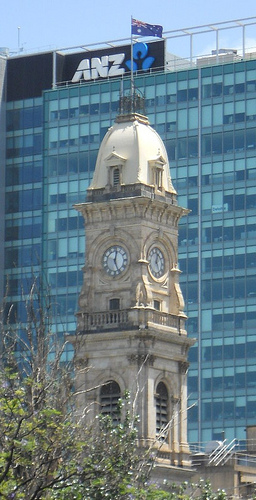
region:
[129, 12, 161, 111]
a national flag and pole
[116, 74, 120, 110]
a communication antenna on top of the tower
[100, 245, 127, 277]
the clock on the clock tower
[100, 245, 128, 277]
the clock display is 12:25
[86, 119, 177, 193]
the clock tower's roof dome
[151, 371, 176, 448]
an archway window with wood blinds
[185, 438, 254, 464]
metal safety hand rails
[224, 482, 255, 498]
a metal fence at the lower end of the clock tower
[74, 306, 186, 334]
a concrete balcony on the clock tower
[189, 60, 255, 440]
a building with many windows in the background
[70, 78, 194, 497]
Clock tower in front of sky scraper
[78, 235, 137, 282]
Clock saying five p.m.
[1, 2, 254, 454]
Sky scraper behind clock tower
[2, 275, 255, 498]
Tree in front of clock tower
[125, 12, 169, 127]
Russian or Canadian flag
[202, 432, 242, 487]
Set of stairs going up to the clock tower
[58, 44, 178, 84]
ANZ building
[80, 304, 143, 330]
Balcony of the clock tower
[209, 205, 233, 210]
Advertisement on the side of the building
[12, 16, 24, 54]
Flag pole on top of building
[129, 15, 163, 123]
Red white and blue flag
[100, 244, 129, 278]
Clock face showing that it is twelve twenty five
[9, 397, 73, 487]
Several tree branches with green leaves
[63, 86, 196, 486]
Old fashion clock tower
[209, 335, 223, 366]
Window on a building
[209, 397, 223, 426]
Window on a building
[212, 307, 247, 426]
Building with several glass windows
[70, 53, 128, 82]
A sign for ANZ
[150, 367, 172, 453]
Open window grate on clock tower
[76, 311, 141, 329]
Railing on side of clock tower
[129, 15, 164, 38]
A flag on top of a building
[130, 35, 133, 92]
The pole holding the flag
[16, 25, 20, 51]
A pole on the roof of a building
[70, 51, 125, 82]
White letters on the building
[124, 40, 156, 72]
A blue sign on a building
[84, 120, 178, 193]
Dome on the tower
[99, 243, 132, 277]
A clock on the tower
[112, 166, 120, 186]
Air ventilation in the tower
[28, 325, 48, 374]
Dry branches next to the tower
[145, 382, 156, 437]
Light shining on the tower side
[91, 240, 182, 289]
clock on the building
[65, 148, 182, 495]
the building is brown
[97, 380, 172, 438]
windows have shutters on them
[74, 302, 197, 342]
balcony on the building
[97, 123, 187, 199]
roof of building is white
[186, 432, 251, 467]
metal railing in distance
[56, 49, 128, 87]
white letters on building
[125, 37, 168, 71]
blue man on building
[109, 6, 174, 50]
blue flag on building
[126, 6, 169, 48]
flag is blue white and red